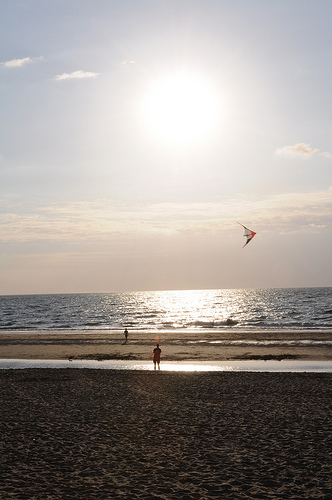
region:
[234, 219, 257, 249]
Kite flying in the sky.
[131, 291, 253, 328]
Sunset reflecting on the water.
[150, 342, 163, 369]
Man standing on the beach.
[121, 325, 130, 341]
Child walking towards the water.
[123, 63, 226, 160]
Sun shining bright in the sky.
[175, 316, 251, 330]
Waves crashing on the beach.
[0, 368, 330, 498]
Sand covering the beach.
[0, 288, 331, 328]
Blue ocean waves reflecting sunlight.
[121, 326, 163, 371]
People standing on the beach.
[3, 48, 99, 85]
Clouds high in the sky.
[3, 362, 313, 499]
Clumpy sand of the beach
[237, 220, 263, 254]
Red white and blue kite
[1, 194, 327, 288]
Grey clouds covering the lower portion of the sky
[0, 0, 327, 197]
Very few clouds near the sun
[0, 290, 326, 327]
Beautiful waves in the water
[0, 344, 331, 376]
Calm water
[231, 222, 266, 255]
Kite flying over the beach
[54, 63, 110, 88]
One of three small clouds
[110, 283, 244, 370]
Reflection of sun in the water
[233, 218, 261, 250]
a kite in the air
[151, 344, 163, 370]
a guy holding the string attached to the kite.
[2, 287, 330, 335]
a blue sea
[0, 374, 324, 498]
sand on the beach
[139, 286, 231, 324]
reflection of the sun on the sea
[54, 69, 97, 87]
a white cloud in the sky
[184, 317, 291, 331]
part of waves on the sea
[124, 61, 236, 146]
a blurred sun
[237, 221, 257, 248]
an orange and white kite flying in the skies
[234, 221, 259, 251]
Kite flying in the sky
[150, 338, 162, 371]
Grown man on the small stream of water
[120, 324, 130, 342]
Child walking near the beach water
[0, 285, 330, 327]
Large blue water with small waves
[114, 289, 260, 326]
Sunset shining off of water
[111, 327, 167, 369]
Two people a man and a boy at the beach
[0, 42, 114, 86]
Two white clouds on the left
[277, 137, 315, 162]
Small white cloud on the right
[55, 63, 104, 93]
The cloud is white.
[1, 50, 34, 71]
The cloud is white.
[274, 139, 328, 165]
The cloud is white.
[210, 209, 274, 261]
The kite is colorful.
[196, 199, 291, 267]
The kite is soaring.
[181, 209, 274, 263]
The kite is airborne.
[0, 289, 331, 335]
The water is rippling.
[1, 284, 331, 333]
The water is wavy.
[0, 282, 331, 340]
The water is pacifying.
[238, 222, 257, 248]
Large kite over the water.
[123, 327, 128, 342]
Smaller walking person on the beach.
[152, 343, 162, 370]
Larger person on the beach.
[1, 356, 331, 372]
Small strip of water going across the beach.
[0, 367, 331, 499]
Largest beach area with many divots in the sand.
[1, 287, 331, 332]
Grey wavy body of water.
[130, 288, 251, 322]
Large illuminated sun spot on the water.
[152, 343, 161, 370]
Person standing in orange and black clothes.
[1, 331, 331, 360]
Smaller strip of sandy beach.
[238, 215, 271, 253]
a kite in air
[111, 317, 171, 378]
people on the beach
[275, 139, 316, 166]
a small cloud in sky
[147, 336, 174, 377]
the person wearing shorts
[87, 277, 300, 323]
the sun on the water